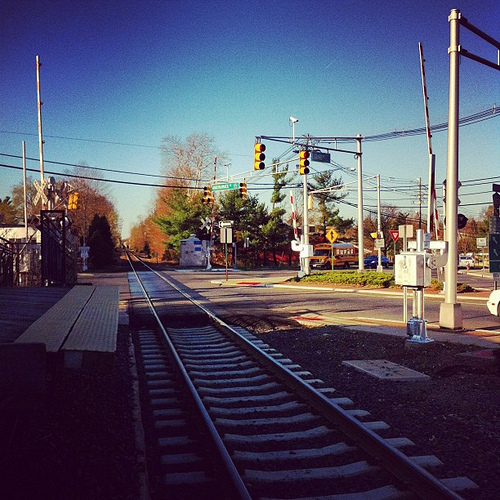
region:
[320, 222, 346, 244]
sign of merging traffic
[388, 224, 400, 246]
red and white sign to yield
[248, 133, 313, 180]
traffic light on red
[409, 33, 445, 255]
gate to stop traffic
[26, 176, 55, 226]
railroad crossing sign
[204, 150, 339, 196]
green with white print street name signs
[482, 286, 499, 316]
front bumber of white car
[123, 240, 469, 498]
a train track crossing a road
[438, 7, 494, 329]
pole that holds traffic lights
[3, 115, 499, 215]
utility lines crisscross the roads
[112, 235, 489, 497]
train tracks going into the distance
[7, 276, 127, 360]
bench next to the train tracks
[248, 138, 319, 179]
two signal lights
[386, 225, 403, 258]
yeild sign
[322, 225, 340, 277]
yellow merge sign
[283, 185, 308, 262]
red and white striped arm that blocks access to railroad tracks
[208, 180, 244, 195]
green sign showing a road name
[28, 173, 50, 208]
railroad crossing sign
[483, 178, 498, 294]
several street signs on the same pole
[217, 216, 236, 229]
one way arrow sign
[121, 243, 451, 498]
a set of train tracks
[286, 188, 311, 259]
a red and white train crossing arm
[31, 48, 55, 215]
a red and white train crossing arm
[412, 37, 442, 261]
a red and white train crossing arm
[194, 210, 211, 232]
a train crossing sign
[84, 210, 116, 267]
a short evergreen tree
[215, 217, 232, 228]
an arrow traffic sign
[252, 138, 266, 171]
an electric traffic signal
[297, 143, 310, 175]
an electric traffic signal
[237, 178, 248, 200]
an electric traffic signal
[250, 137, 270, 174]
yellow traffic light above a street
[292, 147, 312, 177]
yellow traffic light above a street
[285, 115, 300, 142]
security traffic camera above street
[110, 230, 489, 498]
some metal train tracks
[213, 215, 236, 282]
street signs on a pole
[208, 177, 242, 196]
green and white street sign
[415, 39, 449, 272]
red and white striped pole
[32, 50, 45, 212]
red and white striped pole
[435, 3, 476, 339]
silver metal pole near street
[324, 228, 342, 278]
yellow street sign on pole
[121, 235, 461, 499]
a long train track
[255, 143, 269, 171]
a yellow street light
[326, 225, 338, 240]
a yellow and black sign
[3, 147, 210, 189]
a long electrical power line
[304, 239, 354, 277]
a small yellow bus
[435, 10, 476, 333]
a tall gray pole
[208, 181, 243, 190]
a green and white sign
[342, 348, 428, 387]
a concrete slab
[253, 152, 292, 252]
a large green tree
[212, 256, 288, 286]
a concrete sidewalk